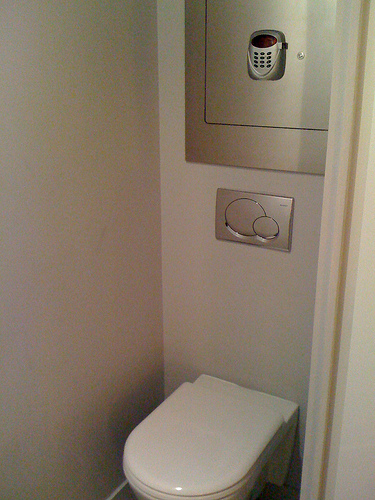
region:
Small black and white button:
[251, 48, 259, 55]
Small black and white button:
[251, 62, 259, 69]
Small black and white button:
[258, 62, 268, 72]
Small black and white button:
[265, 62, 274, 68]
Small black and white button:
[251, 58, 259, 62]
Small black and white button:
[257, 56, 265, 66]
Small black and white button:
[265, 58, 285, 68]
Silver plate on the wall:
[199, 180, 322, 259]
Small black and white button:
[264, 51, 273, 61]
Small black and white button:
[248, 48, 278, 80]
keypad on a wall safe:
[235, 25, 288, 77]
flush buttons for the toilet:
[204, 180, 296, 252]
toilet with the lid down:
[119, 378, 283, 495]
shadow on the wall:
[92, 355, 168, 417]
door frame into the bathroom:
[308, 207, 351, 486]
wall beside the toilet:
[38, 130, 129, 331]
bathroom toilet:
[122, 383, 290, 497]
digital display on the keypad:
[252, 35, 276, 47]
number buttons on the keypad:
[252, 49, 273, 70]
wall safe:
[169, 15, 329, 183]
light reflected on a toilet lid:
[166, 475, 186, 495]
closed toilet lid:
[116, 366, 298, 499]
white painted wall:
[202, 283, 270, 321]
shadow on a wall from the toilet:
[113, 351, 161, 392]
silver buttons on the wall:
[210, 180, 294, 255]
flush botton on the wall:
[217, 187, 295, 256]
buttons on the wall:
[240, 30, 293, 84]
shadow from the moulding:
[324, 283, 354, 323]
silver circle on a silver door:
[292, 42, 312, 67]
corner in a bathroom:
[116, 276, 176, 324]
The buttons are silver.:
[210, 186, 313, 264]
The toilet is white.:
[111, 367, 295, 492]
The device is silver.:
[242, 28, 289, 80]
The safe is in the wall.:
[182, 1, 345, 166]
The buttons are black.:
[244, 44, 273, 76]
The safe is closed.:
[181, 16, 329, 175]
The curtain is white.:
[304, 59, 373, 499]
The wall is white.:
[2, 60, 219, 414]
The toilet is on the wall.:
[99, 344, 311, 497]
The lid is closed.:
[100, 344, 291, 496]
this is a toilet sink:
[134, 392, 285, 499]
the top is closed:
[167, 377, 237, 464]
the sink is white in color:
[162, 419, 238, 474]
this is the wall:
[47, 170, 150, 284]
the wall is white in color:
[0, 176, 146, 349]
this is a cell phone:
[239, 30, 292, 81]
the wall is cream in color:
[15, 269, 145, 355]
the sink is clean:
[151, 403, 248, 497]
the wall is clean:
[40, 195, 147, 311]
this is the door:
[315, 217, 361, 287]